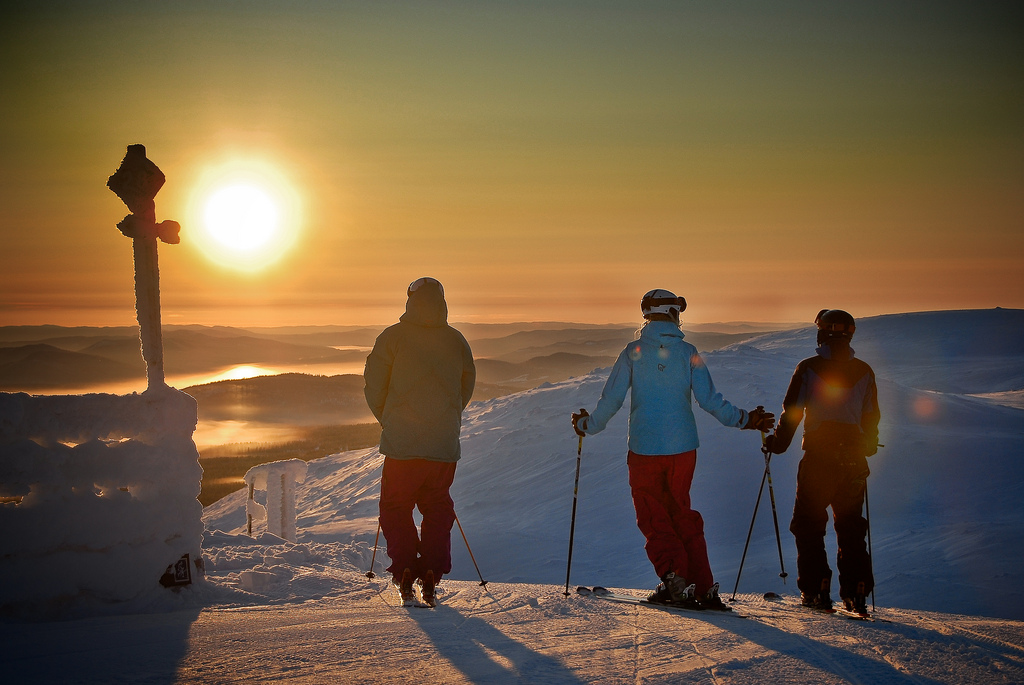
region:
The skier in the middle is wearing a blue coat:
[561, 277, 774, 623]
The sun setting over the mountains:
[179, 138, 353, 440]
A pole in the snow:
[92, 127, 191, 432]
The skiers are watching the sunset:
[314, 259, 903, 634]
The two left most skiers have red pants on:
[333, 274, 770, 619]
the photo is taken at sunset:
[13, 111, 1019, 680]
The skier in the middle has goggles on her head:
[526, 265, 774, 610]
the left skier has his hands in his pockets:
[314, 247, 504, 614]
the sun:
[187, 153, 323, 284]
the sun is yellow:
[192, 177, 295, 258]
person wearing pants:
[380, 460, 473, 590]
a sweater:
[377, 323, 460, 438]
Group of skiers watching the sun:
[291, 244, 930, 681]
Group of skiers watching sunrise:
[327, 218, 948, 671]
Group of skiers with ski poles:
[298, 212, 935, 683]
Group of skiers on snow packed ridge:
[296, 242, 987, 655]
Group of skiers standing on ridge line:
[321, 237, 931, 681]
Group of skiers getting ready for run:
[318, 252, 926, 664]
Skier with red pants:
[324, 241, 528, 641]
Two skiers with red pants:
[343, 228, 752, 649]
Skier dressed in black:
[737, 268, 931, 639]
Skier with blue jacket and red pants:
[532, 246, 790, 655]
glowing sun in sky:
[0, 3, 1019, 301]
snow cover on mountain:
[224, 306, 1019, 610]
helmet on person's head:
[639, 290, 682, 326]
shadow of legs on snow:
[411, 604, 573, 682]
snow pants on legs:
[628, 449, 714, 587]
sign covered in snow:
[104, 144, 180, 392]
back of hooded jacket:
[579, 321, 747, 458]